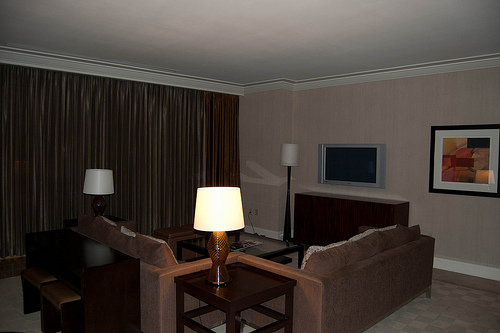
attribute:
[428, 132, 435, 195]
frame — dark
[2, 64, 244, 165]
curtains — brown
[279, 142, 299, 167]
lamp shade — white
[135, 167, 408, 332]
table — end, brown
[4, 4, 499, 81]
ceiling — white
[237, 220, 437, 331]
sofa — brown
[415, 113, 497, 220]
frame — picture